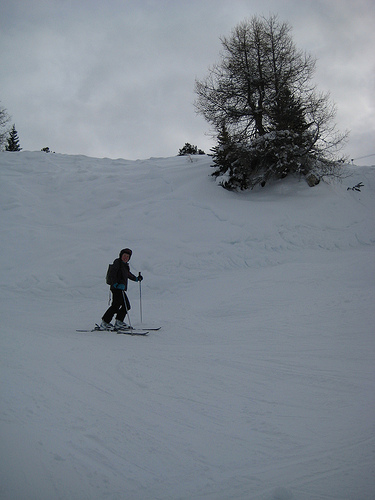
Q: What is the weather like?
A: It is cloudy.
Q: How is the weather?
A: It is cloudy.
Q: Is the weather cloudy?
A: Yes, it is cloudy.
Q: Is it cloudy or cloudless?
A: It is cloudy.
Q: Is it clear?
A: No, it is cloudy.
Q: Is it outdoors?
A: Yes, it is outdoors.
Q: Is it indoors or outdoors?
A: It is outdoors.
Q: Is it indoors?
A: No, it is outdoors.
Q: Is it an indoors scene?
A: No, it is outdoors.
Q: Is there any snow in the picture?
A: Yes, there is snow.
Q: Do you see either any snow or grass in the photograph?
A: Yes, there is snow.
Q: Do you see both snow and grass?
A: No, there is snow but no grass.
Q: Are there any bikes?
A: No, there are no bikes.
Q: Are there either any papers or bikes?
A: No, there are no bikes or papers.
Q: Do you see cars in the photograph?
A: No, there are no cars.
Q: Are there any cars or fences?
A: No, there are no cars or fences.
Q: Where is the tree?
A: The tree is in the snow.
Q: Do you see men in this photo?
A: No, there are no men.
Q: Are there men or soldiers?
A: No, there are no men or soldiers.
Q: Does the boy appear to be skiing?
A: Yes, the boy is skiing.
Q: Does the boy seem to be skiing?
A: Yes, the boy is skiing.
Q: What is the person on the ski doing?
A: The boy is skiing.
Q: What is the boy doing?
A: The boy is skiing.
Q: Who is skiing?
A: The boy is skiing.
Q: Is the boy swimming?
A: No, the boy is skiing.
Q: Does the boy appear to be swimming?
A: No, the boy is skiing.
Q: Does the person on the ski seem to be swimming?
A: No, the boy is skiing.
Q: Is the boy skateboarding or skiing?
A: The boy is skiing.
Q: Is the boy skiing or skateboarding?
A: The boy is skiing.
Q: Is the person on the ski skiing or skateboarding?
A: The boy is skiing.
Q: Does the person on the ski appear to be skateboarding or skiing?
A: The boy is skiing.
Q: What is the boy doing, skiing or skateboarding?
A: The boy is skiing.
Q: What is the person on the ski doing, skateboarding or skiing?
A: The boy is skiing.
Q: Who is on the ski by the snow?
A: The boy is on the ski.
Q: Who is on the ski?
A: The boy is on the ski.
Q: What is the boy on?
A: The boy is on the ski.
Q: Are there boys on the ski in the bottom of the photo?
A: Yes, there is a boy on the ski.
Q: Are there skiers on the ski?
A: No, there is a boy on the ski.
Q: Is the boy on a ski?
A: Yes, the boy is on a ski.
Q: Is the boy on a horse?
A: No, the boy is on a ski.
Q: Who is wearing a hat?
A: The boy is wearing a hat.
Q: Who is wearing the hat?
A: The boy is wearing a hat.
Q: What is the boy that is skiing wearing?
A: The boy is wearing a hat.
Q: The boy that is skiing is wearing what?
A: The boy is wearing a hat.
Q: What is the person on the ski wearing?
A: The boy is wearing a hat.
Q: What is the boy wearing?
A: The boy is wearing a hat.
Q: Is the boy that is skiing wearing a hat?
A: Yes, the boy is wearing a hat.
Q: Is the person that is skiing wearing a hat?
A: Yes, the boy is wearing a hat.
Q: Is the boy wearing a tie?
A: No, the boy is wearing a hat.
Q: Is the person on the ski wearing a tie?
A: No, the boy is wearing a hat.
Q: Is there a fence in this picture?
A: No, there are no fences.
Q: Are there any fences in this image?
A: No, there are no fences.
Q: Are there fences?
A: No, there are no fences.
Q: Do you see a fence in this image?
A: No, there are no fences.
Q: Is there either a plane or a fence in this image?
A: No, there are no fences or airplanes.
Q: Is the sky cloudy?
A: Yes, the sky is cloudy.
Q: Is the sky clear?
A: No, the sky is cloudy.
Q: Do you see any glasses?
A: No, there are no glasses.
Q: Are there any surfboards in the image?
A: No, there are no surfboards.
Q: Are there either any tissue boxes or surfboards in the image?
A: No, there are no surfboards or tissue boxes.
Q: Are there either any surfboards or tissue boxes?
A: No, there are no surfboards or tissue boxes.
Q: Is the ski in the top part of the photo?
A: No, the ski is in the bottom of the image.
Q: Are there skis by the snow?
A: Yes, there is a ski by the snow.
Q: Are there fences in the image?
A: No, there are no fences.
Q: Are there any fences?
A: No, there are no fences.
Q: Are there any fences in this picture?
A: No, there are no fences.